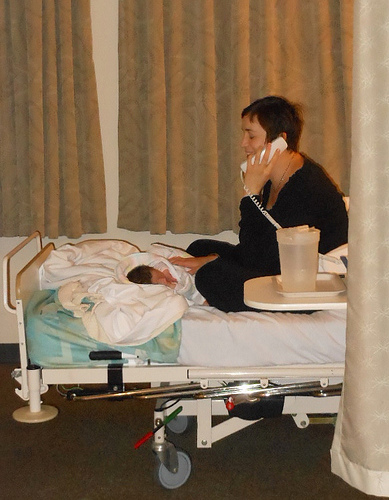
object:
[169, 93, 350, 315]
woman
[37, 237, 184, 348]
turquoise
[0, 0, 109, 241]
curtain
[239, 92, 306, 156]
hair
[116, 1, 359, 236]
curtain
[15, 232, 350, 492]
bed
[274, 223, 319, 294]
pitcher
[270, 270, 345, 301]
tray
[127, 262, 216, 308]
baby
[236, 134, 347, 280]
phone